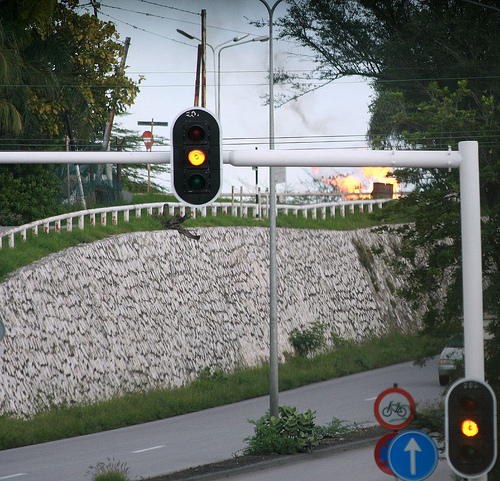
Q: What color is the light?
A: Yellow.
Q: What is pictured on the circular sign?
A: A bicycle.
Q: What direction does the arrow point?
A: Up.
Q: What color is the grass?
A: Green.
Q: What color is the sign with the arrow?
A: Blue and white.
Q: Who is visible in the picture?
A: Nobody.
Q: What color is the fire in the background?
A: Orange and yellow.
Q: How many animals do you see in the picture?
A: None.